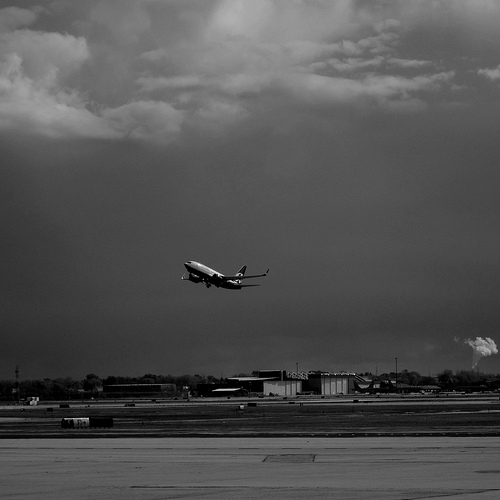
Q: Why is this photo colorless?
A: A black and white filter.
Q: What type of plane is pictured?
A: Commercial plane.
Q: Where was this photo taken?
A: At an airport.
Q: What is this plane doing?
A: Taking off.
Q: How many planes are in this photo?
A: One.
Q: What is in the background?
A: The sky.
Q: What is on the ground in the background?
A: A building.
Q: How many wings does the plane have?
A: Two.